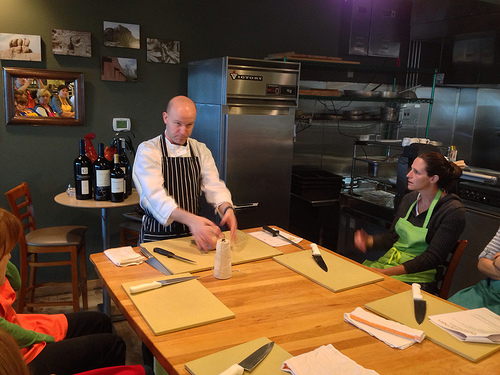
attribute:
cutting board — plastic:
[139, 227, 283, 274]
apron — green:
[366, 187, 456, 279]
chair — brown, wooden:
[3, 182, 95, 307]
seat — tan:
[21, 218, 89, 245]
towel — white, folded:
[95, 237, 200, 292]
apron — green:
[361, 190, 452, 292]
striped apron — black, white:
[135, 130, 203, 249]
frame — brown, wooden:
[4, 65, 105, 160]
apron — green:
[381, 203, 442, 270]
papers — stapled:
[427, 301, 498, 344]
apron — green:
[364, 190, 441, 291]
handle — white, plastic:
[307, 241, 322, 256]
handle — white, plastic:
[410, 281, 423, 301]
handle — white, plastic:
[127, 281, 163, 296]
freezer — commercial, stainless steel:
[184, 56, 299, 229]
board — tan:
[121, 272, 234, 334]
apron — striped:
[138, 135, 208, 236]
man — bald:
[121, 63, 224, 285]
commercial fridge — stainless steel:
[179, 53, 301, 223]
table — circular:
[42, 171, 159, 223]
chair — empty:
[3, 180, 89, 312]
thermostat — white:
[112, 116, 130, 131]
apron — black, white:
[142, 130, 203, 240]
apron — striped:
[128, 135, 215, 245]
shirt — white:
[129, 133, 237, 233]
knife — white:
[411, 281, 426, 324]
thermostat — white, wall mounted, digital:
[106, 113, 133, 131]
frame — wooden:
[0, 65, 88, 127]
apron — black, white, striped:
[139, 129, 202, 244]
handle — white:
[128, 278, 162, 295]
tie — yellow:
[385, 244, 417, 264]